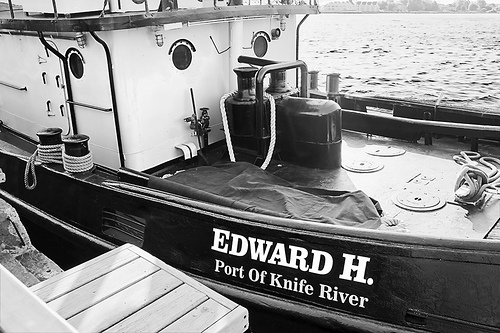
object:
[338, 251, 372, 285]
letter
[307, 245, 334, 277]
letter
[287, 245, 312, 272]
r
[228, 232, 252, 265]
d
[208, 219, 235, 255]
e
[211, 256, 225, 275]
p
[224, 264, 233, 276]
o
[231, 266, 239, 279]
r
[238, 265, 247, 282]
t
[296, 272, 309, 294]
letter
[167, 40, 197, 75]
portal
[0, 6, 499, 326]
boat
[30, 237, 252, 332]
stone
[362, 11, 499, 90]
river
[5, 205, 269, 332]
dock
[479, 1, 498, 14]
trees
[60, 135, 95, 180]
rope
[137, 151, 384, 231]
tarp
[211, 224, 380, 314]
name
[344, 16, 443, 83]
sunlight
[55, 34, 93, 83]
portholes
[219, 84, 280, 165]
rope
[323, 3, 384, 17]
boat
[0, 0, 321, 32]
roof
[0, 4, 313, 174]
cabin